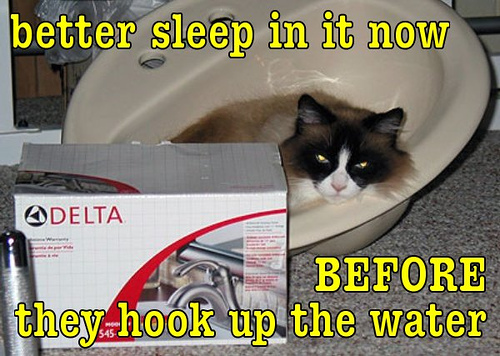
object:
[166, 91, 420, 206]
cat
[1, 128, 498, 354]
floor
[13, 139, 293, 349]
box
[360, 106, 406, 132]
ears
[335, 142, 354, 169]
streak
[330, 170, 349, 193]
nose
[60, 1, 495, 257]
sink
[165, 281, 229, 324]
faucet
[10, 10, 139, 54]
writing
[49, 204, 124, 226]
writing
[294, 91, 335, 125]
ear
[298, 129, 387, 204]
face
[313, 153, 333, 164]
eyes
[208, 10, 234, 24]
hole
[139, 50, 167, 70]
hole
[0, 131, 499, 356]
countertop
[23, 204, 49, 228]
logo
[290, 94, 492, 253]
edge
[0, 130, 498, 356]
carpet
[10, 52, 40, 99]
wood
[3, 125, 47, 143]
part